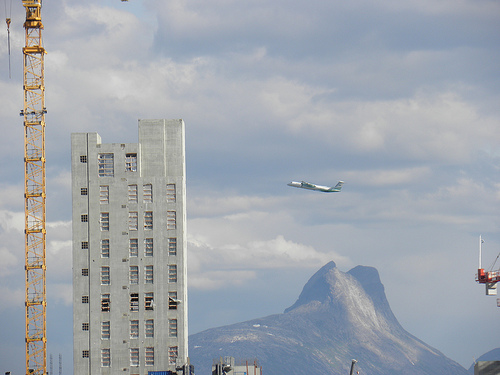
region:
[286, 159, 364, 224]
this is a plane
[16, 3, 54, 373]
this is a ladder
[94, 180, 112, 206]
this is a window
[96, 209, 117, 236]
this is a window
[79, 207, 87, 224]
this is a window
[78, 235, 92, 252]
this is a window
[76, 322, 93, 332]
this is a window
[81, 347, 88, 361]
this is a window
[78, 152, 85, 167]
this is a window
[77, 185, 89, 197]
this is a window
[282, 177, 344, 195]
airplane flying in the sky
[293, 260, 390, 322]
tall, peaked mountain top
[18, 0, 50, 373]
tall, yellow construction equipment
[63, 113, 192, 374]
gray building under construction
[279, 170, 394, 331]
airplane above a mountain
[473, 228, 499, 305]
red and white construction equipment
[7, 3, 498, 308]
white clouds in the sky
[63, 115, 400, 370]
building next to a mountain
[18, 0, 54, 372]
yellow construction equipment near a building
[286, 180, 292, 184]
nose of the airplane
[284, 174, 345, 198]
an airplane flying in the air.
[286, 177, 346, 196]
An airplane in the sky.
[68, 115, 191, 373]
A big gray tower.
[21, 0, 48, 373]
A tall yellow crane.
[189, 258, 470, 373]
A mountain with a high peak.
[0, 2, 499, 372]
White clouds in the sky.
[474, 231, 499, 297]
Part of a crane.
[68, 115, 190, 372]
A tall building with windows.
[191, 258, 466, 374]
A mountain with a steep slope.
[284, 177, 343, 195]
A plane flying in the sky.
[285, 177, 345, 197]
A jet in the sky.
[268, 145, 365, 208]
the plane is ascending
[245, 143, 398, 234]
the plane is flying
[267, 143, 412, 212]
the jet is in the sky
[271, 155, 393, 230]
a passenger jet ascending in the sky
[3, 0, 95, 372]
a large yellow tower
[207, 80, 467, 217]
a plane amongst the clouds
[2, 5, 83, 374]
this is a large crane structure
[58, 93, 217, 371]
a large cement building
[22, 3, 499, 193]
there are thick clouds in the sky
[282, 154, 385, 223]
the plane is white and blue